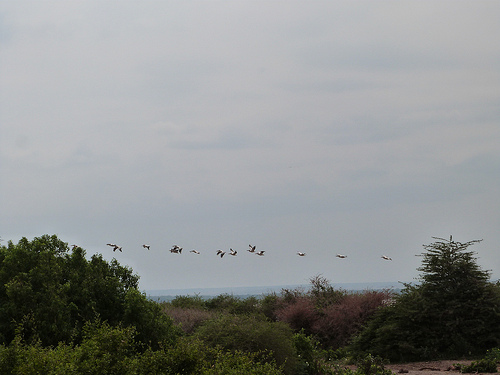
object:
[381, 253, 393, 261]
bird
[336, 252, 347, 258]
bird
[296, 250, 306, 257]
bird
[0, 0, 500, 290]
sky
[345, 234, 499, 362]
bush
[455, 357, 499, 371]
shrubs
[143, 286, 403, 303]
sea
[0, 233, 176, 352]
tree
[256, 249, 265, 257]
bird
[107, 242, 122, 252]
bird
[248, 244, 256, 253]
bird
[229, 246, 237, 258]
bird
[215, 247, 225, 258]
bird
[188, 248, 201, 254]
bird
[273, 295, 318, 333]
bushes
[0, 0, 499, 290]
clouds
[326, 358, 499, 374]
dirt